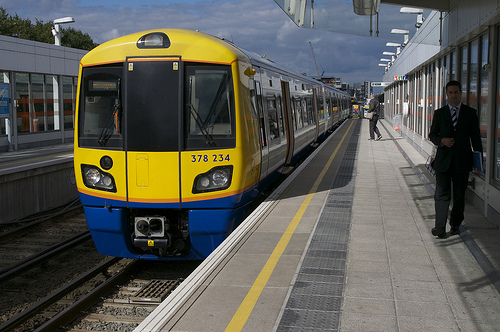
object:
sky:
[0, 0, 433, 85]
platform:
[0, 141, 76, 176]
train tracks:
[2, 227, 125, 332]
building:
[0, 34, 89, 152]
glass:
[270, 98, 276, 128]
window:
[183, 67, 234, 136]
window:
[253, 78, 269, 150]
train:
[71, 25, 353, 262]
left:
[0, 0, 96, 332]